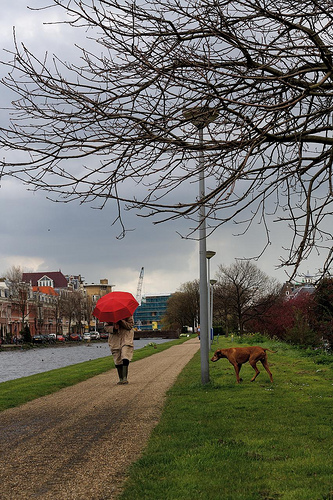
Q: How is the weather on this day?
A: It is overcast.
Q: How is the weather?
A: It is overcast.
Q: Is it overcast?
A: Yes, it is overcast.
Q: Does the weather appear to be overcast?
A: Yes, it is overcast.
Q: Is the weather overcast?
A: Yes, it is overcast.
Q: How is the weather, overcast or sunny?
A: It is overcast.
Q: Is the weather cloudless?
A: No, it is overcast.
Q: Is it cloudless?
A: No, it is overcast.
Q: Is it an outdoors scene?
A: Yes, it is outdoors.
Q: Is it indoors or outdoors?
A: It is outdoors.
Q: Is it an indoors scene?
A: No, it is outdoors.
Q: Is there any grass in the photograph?
A: Yes, there is grass.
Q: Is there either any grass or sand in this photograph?
A: Yes, there is grass.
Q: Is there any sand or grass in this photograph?
A: Yes, there is grass.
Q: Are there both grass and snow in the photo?
A: No, there is grass but no snow.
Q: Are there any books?
A: No, there are no books.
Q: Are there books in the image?
A: No, there are no books.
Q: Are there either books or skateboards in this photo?
A: No, there are no books or skateboards.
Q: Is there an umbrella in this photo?
A: Yes, there is an umbrella.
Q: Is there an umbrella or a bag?
A: Yes, there is an umbrella.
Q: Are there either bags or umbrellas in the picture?
A: Yes, there is an umbrella.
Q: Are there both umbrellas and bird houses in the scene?
A: No, there is an umbrella but no bird houses.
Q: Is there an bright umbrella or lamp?
A: Yes, there is a bright umbrella.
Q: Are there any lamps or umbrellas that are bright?
A: Yes, the umbrella is bright.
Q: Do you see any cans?
A: No, there are no cans.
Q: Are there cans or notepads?
A: No, there are no cans or notepads.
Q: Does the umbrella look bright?
A: Yes, the umbrella is bright.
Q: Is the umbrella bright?
A: Yes, the umbrella is bright.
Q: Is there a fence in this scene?
A: No, there are no fences.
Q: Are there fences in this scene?
A: No, there are no fences.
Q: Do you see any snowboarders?
A: No, there are no snowboarders.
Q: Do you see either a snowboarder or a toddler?
A: No, there are no snowboarders or toddlers.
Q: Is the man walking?
A: Yes, the man is walking.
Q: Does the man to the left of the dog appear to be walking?
A: Yes, the man is walking.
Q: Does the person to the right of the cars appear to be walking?
A: Yes, the man is walking.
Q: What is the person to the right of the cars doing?
A: The man is walking.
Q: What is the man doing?
A: The man is walking.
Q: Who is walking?
A: The man is walking.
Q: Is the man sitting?
A: No, the man is walking.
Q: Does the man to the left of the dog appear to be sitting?
A: No, the man is walking.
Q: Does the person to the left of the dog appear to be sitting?
A: No, the man is walking.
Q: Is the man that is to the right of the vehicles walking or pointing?
A: The man is walking.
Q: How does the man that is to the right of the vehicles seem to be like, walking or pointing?
A: The man is walking.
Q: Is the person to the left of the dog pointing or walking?
A: The man is walking.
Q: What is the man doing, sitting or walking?
A: The man is walking.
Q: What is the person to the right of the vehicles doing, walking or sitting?
A: The man is walking.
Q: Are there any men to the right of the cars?
A: Yes, there is a man to the right of the cars.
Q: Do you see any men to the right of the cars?
A: Yes, there is a man to the right of the cars.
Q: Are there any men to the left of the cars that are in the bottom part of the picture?
A: No, the man is to the right of the cars.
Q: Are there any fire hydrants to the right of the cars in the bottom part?
A: No, there is a man to the right of the cars.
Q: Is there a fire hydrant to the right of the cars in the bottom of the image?
A: No, there is a man to the right of the cars.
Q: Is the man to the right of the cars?
A: Yes, the man is to the right of the cars.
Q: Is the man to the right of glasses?
A: No, the man is to the right of the cars.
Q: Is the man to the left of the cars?
A: No, the man is to the right of the cars.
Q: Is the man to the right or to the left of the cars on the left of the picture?
A: The man is to the right of the cars.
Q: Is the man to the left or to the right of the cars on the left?
A: The man is to the right of the cars.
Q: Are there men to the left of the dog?
A: Yes, there is a man to the left of the dog.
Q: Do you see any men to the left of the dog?
A: Yes, there is a man to the left of the dog.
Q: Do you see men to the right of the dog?
A: No, the man is to the left of the dog.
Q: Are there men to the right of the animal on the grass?
A: No, the man is to the left of the dog.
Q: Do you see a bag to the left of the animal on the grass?
A: No, there is a man to the left of the dog.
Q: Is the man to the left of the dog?
A: Yes, the man is to the left of the dog.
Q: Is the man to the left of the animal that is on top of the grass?
A: Yes, the man is to the left of the dog.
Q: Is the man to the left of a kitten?
A: No, the man is to the left of the dog.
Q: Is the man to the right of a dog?
A: No, the man is to the left of a dog.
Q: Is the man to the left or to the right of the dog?
A: The man is to the left of the dog.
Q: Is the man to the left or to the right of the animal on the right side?
A: The man is to the left of the dog.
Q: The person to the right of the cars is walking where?
A: The man is walking on the sidewalk.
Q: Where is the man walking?
A: The man is walking on the sidewalk.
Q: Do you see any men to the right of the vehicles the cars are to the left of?
A: Yes, there is a man to the right of the vehicles.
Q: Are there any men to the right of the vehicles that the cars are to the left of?
A: Yes, there is a man to the right of the vehicles.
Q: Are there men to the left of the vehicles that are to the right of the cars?
A: No, the man is to the right of the vehicles.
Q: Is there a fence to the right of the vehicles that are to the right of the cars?
A: No, there is a man to the right of the vehicles.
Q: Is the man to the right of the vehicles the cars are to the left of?
A: Yes, the man is to the right of the vehicles.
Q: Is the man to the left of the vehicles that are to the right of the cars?
A: No, the man is to the right of the vehicles.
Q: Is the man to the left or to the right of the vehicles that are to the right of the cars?
A: The man is to the right of the vehicles.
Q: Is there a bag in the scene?
A: No, there are no bags.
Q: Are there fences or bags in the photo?
A: No, there are no bags or fences.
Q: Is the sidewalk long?
A: Yes, the sidewalk is long.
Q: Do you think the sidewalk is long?
A: Yes, the sidewalk is long.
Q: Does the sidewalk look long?
A: Yes, the sidewalk is long.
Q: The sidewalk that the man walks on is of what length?
A: The side walk is long.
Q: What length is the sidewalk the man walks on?
A: The side walk is long.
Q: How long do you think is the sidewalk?
A: The sidewalk is long.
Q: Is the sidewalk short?
A: No, the sidewalk is long.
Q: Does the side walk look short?
A: No, the side walk is long.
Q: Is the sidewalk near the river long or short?
A: The sidewalk is long.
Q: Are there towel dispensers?
A: No, there are no towel dispensers.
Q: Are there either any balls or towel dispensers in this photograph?
A: No, there are no towel dispensers or balls.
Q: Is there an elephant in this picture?
A: No, there are no elephants.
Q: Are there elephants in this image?
A: No, there are no elephants.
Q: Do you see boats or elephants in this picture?
A: No, there are no elephants or boats.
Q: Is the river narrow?
A: Yes, the river is narrow.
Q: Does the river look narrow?
A: Yes, the river is narrow.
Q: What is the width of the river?
A: The river is narrow.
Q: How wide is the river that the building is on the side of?
A: The river is narrow.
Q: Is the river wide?
A: No, the river is narrow.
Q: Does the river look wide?
A: No, the river is narrow.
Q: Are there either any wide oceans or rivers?
A: No, there is a river but it is narrow.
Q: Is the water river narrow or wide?
A: The river is narrow.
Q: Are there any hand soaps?
A: No, there are no hand soaps.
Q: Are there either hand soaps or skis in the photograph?
A: No, there are no hand soaps or skis.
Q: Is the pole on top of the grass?
A: Yes, the pole is on top of the grass.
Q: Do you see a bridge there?
A: Yes, there is a bridge.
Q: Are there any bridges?
A: Yes, there is a bridge.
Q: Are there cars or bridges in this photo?
A: Yes, there is a bridge.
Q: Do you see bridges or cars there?
A: Yes, there is a bridge.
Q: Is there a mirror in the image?
A: No, there are no mirrors.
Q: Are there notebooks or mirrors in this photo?
A: No, there are no mirrors or notebooks.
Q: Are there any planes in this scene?
A: No, there are no planes.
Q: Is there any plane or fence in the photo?
A: No, there are no airplanes or fences.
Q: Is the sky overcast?
A: Yes, the sky is overcast.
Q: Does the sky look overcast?
A: Yes, the sky is overcast.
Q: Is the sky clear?
A: No, the sky is overcast.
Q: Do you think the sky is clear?
A: No, the sky is overcast.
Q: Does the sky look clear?
A: No, the sky is overcast.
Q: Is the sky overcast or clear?
A: The sky is overcast.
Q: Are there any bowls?
A: No, there are no bowls.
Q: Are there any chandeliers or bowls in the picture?
A: No, there are no bowls or chandeliers.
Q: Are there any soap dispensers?
A: No, there are no soap dispensers.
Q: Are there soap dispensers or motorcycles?
A: No, there are no soap dispensers or motorcycles.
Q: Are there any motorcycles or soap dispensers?
A: No, there are no soap dispensers or motorcycles.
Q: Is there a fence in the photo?
A: No, there are no fences.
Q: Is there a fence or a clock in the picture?
A: No, there are no fences or clocks.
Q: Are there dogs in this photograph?
A: Yes, there is a dog.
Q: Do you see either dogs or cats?
A: Yes, there is a dog.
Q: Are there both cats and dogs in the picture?
A: No, there is a dog but no cats.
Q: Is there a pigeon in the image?
A: No, there are no pigeons.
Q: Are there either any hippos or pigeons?
A: No, there are no pigeons or hippos.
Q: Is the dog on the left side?
A: No, the dog is on the right of the image.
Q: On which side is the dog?
A: The dog is on the right of the image.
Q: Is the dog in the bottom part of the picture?
A: Yes, the dog is in the bottom of the image.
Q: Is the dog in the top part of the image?
A: No, the dog is in the bottom of the image.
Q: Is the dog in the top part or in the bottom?
A: The dog is in the bottom of the image.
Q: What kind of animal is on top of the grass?
A: The animal is a dog.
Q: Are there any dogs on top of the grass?
A: Yes, there is a dog on top of the grass.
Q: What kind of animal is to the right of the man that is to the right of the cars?
A: The animal is a dog.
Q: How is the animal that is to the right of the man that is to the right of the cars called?
A: The animal is a dog.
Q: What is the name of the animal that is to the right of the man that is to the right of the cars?
A: The animal is a dog.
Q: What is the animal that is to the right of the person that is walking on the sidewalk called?
A: The animal is a dog.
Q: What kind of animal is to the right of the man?
A: The animal is a dog.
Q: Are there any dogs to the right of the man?
A: Yes, there is a dog to the right of the man.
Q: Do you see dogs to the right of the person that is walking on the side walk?
A: Yes, there is a dog to the right of the man.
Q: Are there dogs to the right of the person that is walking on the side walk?
A: Yes, there is a dog to the right of the man.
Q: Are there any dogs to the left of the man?
A: No, the dog is to the right of the man.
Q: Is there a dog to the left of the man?
A: No, the dog is to the right of the man.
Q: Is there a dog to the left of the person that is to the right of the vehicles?
A: No, the dog is to the right of the man.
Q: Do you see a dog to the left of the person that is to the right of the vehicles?
A: No, the dog is to the right of the man.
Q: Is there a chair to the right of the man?
A: No, there is a dog to the right of the man.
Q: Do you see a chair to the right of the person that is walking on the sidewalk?
A: No, there is a dog to the right of the man.